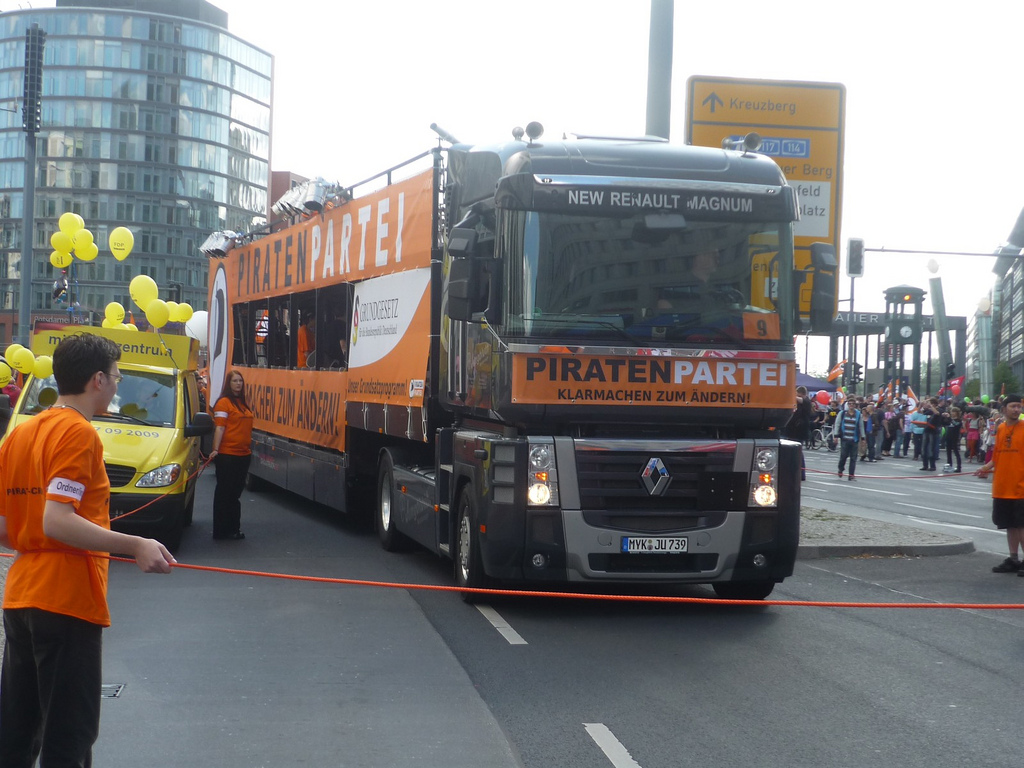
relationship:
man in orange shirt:
[0, 324, 130, 764] [0, 403, 124, 635]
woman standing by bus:
[202, 367, 259, 541] [198, 119, 805, 598]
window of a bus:
[491, 204, 793, 354] [198, 119, 805, 598]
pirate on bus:
[526, 357, 647, 383] [198, 119, 805, 598]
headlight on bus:
[519, 443, 565, 513] [198, 119, 805, 598]